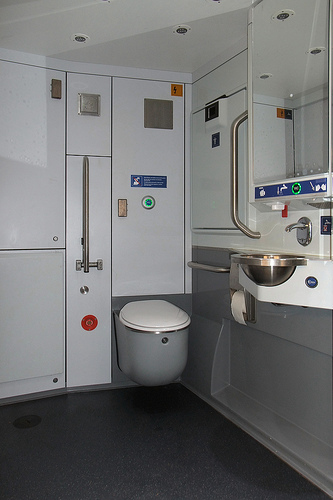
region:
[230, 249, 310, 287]
Brushed steel sink basin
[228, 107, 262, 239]
Brushed steel handle on a door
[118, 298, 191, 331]
Toilet seat with the lid down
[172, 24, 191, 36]
A light fixture in the ceiling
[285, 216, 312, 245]
Steel faucet of a sink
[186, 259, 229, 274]
A steel handle on the wall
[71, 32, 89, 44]
Light fixture in a ceiling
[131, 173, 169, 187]
Warning sticker on a door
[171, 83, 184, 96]
Cautionary sticker on a wall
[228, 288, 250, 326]
Roll of toilet paper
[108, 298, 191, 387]
a toilet in a bathroom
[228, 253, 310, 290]
a metal sink in a bathroom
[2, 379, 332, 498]
a black floor in the bathroom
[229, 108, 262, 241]
a long metal handle on the wall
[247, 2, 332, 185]
a mirror in the bathroom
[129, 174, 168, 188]
a blue sticker with text on a wall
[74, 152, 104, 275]
a long metal handle on a wall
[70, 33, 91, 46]
a light on a ceiling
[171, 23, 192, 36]
a light on a ceiling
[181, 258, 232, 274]
a long metal handle on a wall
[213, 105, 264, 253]
a silver metal handle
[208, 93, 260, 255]
a silver metal handle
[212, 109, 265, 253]
a silver metal handle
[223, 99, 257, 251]
a silver metal handle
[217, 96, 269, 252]
a silver metal handle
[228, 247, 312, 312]
a small metal sink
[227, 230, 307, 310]
a small metal sink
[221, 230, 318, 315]
a small metal sink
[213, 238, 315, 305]
a small metal sink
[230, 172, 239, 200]
a metal pole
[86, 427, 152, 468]
the floor is grey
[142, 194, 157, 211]
a green button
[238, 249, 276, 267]
a sink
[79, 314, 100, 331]
a red circle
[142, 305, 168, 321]
a lid on the toilt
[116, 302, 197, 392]
a toilet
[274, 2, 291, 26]
light in the ceiling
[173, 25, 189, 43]
vent in the ceiling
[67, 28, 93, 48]
vent in the ceiling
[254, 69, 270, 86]
vent in the ceiling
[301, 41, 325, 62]
vent in the ceiling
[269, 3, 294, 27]
vent in the ceiling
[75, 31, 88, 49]
vent in the ceiling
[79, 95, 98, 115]
square on the wall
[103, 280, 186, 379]
toilet in the wall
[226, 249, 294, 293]
sink on the wall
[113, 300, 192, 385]
Toilet bowl with lid closed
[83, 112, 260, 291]
Handles for people who need assistance in the bathroom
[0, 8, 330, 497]
Bathroom with sink and toilet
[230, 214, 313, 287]
Sink and faucet in bathroom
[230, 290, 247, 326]
Roll of toilet paper in bathroom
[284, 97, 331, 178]
Mirror in the bathroom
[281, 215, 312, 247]
Faucet for dispensing water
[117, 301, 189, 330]
Lid of toilet in bathroom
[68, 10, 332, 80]
Lights in ceiling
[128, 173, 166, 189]
Sign of what not to put in the toilet